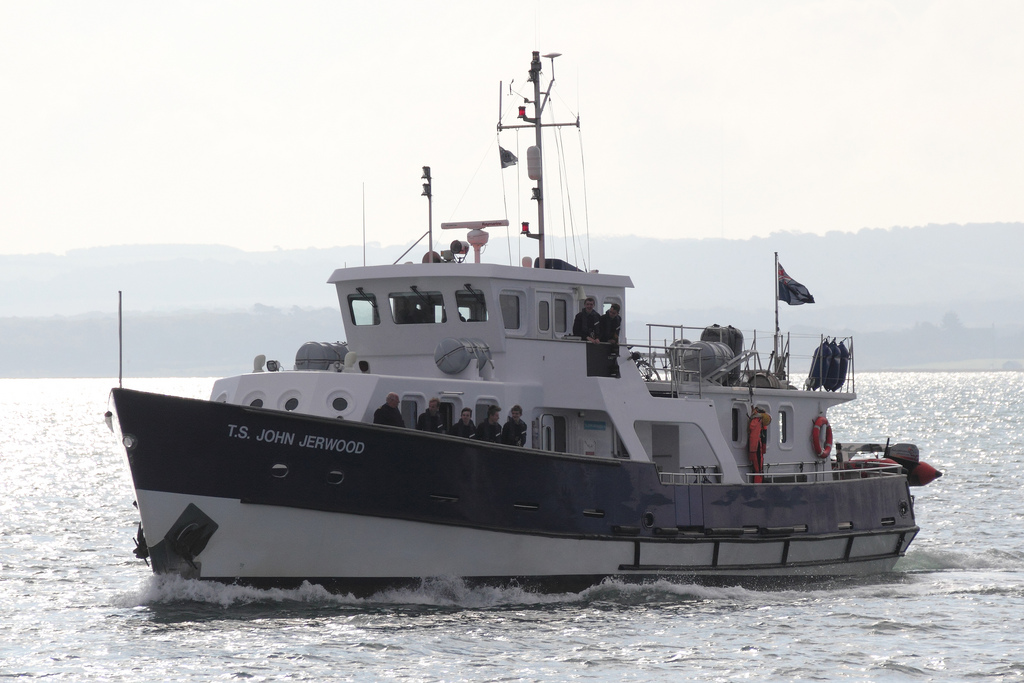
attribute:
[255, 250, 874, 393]
level — upper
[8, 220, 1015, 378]
shoreline — hilly